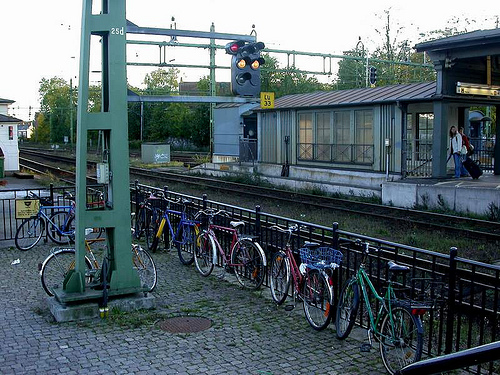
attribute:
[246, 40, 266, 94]
traffic light — yellow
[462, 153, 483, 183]
luggage — black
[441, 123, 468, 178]
woman — in white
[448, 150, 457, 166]
ground — back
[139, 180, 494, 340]
railing — black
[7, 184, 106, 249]
bike — blue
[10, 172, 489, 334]
fencing — black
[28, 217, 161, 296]
bike — yellow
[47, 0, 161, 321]
structure — green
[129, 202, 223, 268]
bicycle — blue, yellow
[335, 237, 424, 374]
greenbike — green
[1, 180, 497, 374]
metal fence — black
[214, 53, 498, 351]
house — white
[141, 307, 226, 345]
manhole — steel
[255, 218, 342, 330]
bicycle — pink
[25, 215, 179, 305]
bike — yellow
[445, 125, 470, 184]
woman — in white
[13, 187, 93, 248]
bike — blue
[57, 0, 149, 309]
metal — green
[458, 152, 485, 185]
suitcase — black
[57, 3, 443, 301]
structure — green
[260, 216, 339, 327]
bike — red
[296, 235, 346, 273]
basket — rear, blue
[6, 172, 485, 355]
fence — black, metal